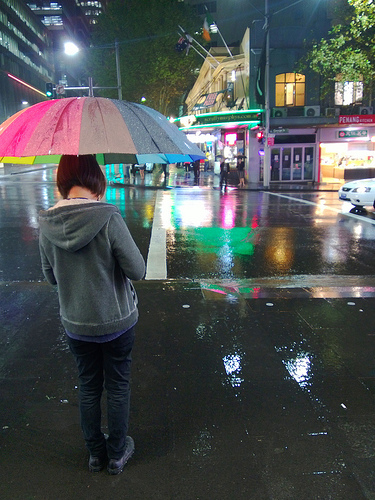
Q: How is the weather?
A: Rainy.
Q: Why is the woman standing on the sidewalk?
A: To look at something in the hands.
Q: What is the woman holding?
A: An umbrella.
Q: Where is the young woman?
A: Standing on the sidewalk.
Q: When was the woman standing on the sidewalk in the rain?
A: Early nighttime.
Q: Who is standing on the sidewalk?
A: A woman holding an umbrella.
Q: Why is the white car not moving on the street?
A: To stop for the red traffic light.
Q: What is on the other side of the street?
A: A convenience store.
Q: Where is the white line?
A: Middle of road.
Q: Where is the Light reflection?
A: Front of woman.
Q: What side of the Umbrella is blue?
A: Right side.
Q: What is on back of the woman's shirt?
A: Gray hood.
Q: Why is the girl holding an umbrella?
A: It's raining.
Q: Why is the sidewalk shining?
A: Rain and light.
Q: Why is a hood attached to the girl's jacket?
A: Protect her head.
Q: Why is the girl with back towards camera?
A: Because girl facing road.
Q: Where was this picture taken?
A: On a street corner.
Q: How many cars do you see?
A: One.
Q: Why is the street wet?
A: It is raining.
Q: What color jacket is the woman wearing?
A: Gray.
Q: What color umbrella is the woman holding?
A: A rainbow umbrella.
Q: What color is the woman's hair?
A: Brown.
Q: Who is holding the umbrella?
A: A woman.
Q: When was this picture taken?
A: At night.